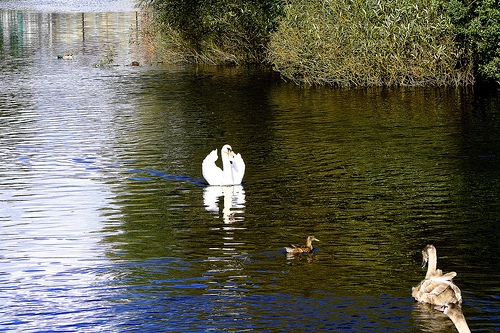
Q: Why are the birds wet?
A: They're in the water.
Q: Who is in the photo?
A: Nobody.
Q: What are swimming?
A: Birds.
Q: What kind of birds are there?
A: Two ducks and a swan.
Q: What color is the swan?
A: White.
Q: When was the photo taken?
A: Daytime.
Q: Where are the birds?
A: In a lake.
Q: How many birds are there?
A: Three.